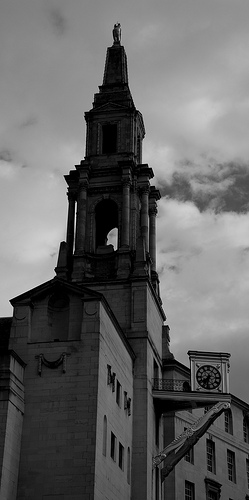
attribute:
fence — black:
[144, 371, 187, 409]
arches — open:
[79, 193, 118, 255]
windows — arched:
[96, 377, 246, 486]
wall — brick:
[17, 315, 126, 498]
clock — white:
[198, 363, 219, 388]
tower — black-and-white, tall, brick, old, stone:
[85, 23, 164, 496]